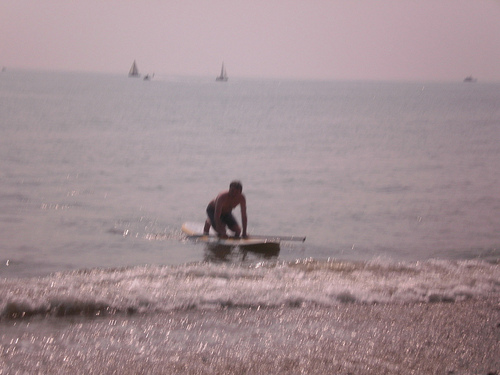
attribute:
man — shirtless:
[203, 177, 250, 241]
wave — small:
[9, 260, 498, 317]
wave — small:
[19, 260, 481, 373]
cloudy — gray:
[253, 6, 443, 63]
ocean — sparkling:
[6, 70, 498, 310]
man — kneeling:
[205, 180, 250, 239]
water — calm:
[30, 97, 474, 173]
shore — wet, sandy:
[292, 306, 495, 370]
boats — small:
[90, 49, 282, 111]